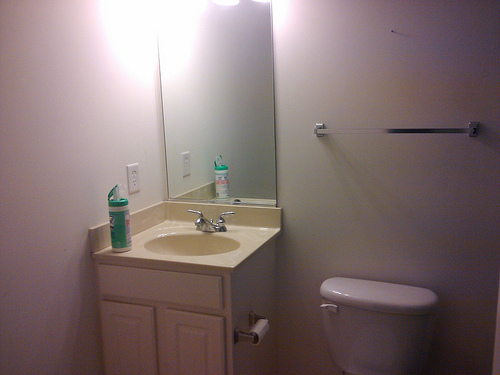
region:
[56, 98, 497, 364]
a picture of a bathroom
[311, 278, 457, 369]
a toilet in the bathroom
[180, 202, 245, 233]
handles on a sink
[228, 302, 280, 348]
a toilet paper roll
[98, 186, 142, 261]
wipes on a counter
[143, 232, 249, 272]
a bathroom sink bowl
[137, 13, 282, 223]
the bathroom mirror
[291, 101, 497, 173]
a towel rack above the toilet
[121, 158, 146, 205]
an electric outlet for appliances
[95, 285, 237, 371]
bathroom cabinet on the sink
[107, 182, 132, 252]
a container of disinfectant wipes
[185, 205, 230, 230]
the water valve fixture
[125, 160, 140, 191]
a beige power outlet cover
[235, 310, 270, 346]
the toilet paper dispenser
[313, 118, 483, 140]
the bathroom towel rack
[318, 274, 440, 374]
the toilet water holding tank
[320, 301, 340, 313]
the toilet flushing handle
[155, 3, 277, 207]
the bathroom wall mirror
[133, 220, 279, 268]
a porcelain bathroom sink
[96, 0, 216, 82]
a reflection of light on the mirror and wall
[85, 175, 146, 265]
open lysol anti bacterial cleaning wipes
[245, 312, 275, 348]
toilet paper holder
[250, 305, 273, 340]
toilet paper roll on holder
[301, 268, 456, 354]
toilet with seat down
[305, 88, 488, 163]
towel rack above toilet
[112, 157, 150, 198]
twin style electrical outlet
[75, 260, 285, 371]
twin door cabinet under the sink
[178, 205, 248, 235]
metal sink faucet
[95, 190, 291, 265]
tan single sink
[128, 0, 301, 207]
bathroom mirror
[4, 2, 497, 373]
A bathroom.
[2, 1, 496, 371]
White colored walls.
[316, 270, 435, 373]
A white toilet.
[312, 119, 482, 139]
A long silver towel rack.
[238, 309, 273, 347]
A silver toilet paper holder.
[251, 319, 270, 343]
A white roll of toilet paper.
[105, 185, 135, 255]
A green and white container of Lysol wipes.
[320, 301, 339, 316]
A white toilet flusher handle.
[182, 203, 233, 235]
Silver sink faucets.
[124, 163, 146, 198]
A white electrical outlet.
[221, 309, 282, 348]
toilet paper in the holder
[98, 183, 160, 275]
the container is green and white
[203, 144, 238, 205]
reflection of container in mirror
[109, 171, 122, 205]
wipes inside the container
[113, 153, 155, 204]
outlet above the counter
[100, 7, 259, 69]
light shining on mirror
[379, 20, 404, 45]
nail hanging in wall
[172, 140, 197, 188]
reflection of outlet in mirror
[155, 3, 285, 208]
mirror hanging above sink